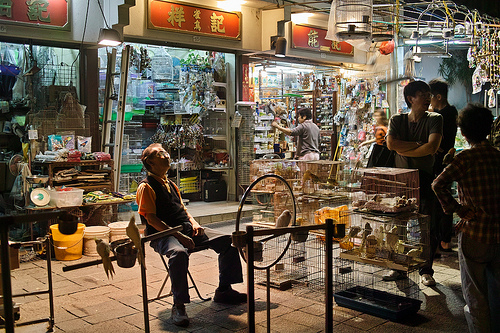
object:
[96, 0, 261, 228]
store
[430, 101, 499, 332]
person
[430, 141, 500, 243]
shirt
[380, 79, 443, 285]
person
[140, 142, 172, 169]
head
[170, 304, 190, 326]
feet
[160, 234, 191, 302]
leg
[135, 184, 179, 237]
arm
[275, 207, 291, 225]
small/yellow finch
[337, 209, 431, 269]
cage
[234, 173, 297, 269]
large/metal hoop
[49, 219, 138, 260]
row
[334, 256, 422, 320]
cage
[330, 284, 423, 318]
bottom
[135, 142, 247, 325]
man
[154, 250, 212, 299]
stool